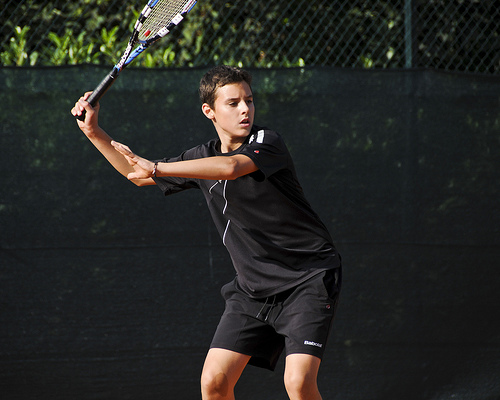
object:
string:
[253, 296, 277, 321]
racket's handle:
[71, 43, 153, 122]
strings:
[137, 0, 186, 31]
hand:
[70, 91, 100, 128]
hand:
[111, 140, 155, 181]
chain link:
[0, 0, 499, 79]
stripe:
[256, 129, 266, 144]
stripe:
[246, 133, 255, 144]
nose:
[239, 96, 250, 115]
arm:
[104, 139, 216, 187]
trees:
[0, 0, 499, 72]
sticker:
[143, 29, 150, 37]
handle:
[75, 68, 118, 121]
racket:
[75, 0, 192, 123]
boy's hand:
[70, 91, 101, 129]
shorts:
[208, 264, 346, 372]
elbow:
[224, 156, 241, 179]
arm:
[158, 131, 276, 188]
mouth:
[239, 117, 251, 128]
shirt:
[145, 124, 340, 298]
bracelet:
[153, 160, 159, 179]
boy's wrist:
[151, 162, 182, 178]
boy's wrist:
[85, 125, 109, 145]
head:
[199, 65, 255, 137]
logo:
[300, 337, 325, 350]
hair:
[199, 64, 252, 110]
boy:
[70, 63, 345, 399]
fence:
[4, 0, 499, 399]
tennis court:
[1, 1, 500, 399]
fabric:
[0, 62, 500, 399]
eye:
[228, 98, 253, 107]